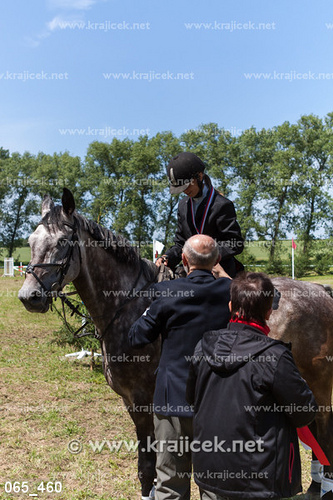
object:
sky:
[0, 0, 332, 242]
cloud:
[0, 0, 333, 152]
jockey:
[156, 154, 243, 287]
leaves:
[237, 177, 251, 204]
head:
[182, 233, 221, 273]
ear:
[42, 195, 54, 214]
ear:
[61, 187, 75, 215]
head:
[19, 188, 81, 314]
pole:
[292, 248, 295, 280]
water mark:
[0, 0, 333, 499]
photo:
[0, 0, 332, 499]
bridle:
[24, 218, 82, 301]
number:
[4, 482, 62, 495]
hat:
[166, 151, 205, 194]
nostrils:
[30, 289, 40, 300]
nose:
[18, 290, 38, 302]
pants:
[154, 402, 191, 500]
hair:
[230, 273, 274, 325]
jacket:
[192, 321, 318, 494]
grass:
[0, 238, 333, 500]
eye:
[58, 238, 68, 247]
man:
[155, 151, 243, 282]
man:
[191, 273, 316, 500]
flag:
[292, 237, 297, 249]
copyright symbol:
[67, 438, 82, 455]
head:
[170, 154, 203, 198]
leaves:
[275, 121, 295, 148]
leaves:
[275, 170, 301, 194]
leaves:
[256, 128, 277, 162]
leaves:
[264, 201, 281, 219]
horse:
[18, 188, 333, 500]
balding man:
[128, 234, 233, 499]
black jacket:
[127, 270, 232, 418]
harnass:
[24, 220, 96, 344]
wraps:
[310, 460, 333, 499]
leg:
[303, 401, 331, 496]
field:
[0, 247, 333, 500]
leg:
[311, 393, 333, 480]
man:
[130, 234, 234, 500]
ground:
[0, 238, 333, 500]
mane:
[42, 205, 158, 280]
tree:
[0, 118, 333, 246]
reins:
[91, 262, 161, 339]